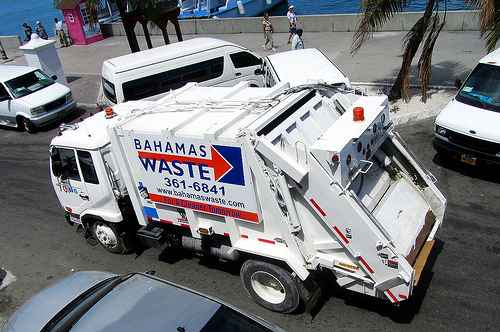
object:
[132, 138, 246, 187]
logo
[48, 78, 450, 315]
truck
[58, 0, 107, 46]
kiosk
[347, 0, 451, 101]
palm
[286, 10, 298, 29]
shirt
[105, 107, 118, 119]
signal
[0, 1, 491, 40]
water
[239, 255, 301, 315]
wheel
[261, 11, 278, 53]
person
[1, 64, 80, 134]
van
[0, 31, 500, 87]
sidewalk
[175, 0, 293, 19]
boat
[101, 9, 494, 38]
wall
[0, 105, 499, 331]
street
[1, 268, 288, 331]
car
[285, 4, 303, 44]
man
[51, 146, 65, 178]
mirror